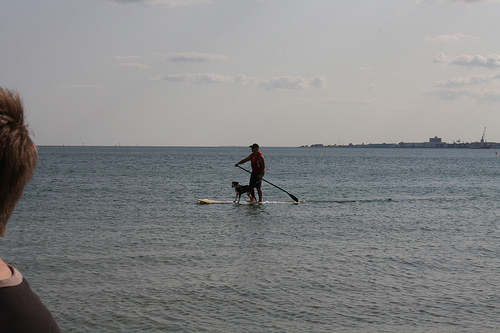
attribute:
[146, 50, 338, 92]
clouds — white 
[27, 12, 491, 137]
sky — blue 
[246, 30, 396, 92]
sky — blue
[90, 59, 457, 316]
person — standing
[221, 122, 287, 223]
person — close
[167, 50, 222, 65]
cloud — white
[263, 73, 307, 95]
cloud — white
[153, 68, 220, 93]
cloud — white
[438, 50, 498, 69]
cloud — white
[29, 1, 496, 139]
sky — blue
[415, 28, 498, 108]
cloud — white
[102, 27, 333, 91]
cloud — white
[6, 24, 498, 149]
sky — blue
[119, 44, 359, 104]
clouds — white